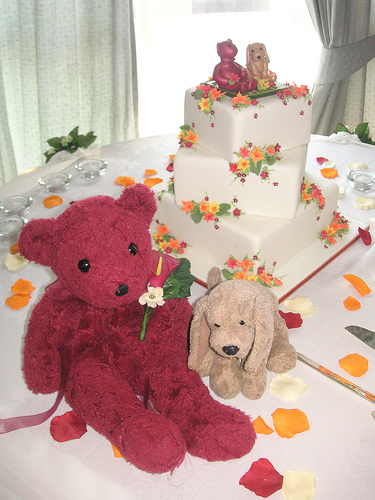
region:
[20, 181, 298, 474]
two plushies on a white tablecloth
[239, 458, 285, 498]
a red rose petal on a tablecloth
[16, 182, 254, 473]
a red teddy bear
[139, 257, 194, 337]
a boutonniere on a red teddy bear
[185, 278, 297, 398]
a plushie dog next to a red teddy bear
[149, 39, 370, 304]
a wedding cake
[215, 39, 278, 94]
figurines of a teddy bear and a dog on top of a wedding cake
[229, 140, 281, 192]
candy flowers on a white wedding cake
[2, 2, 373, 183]
gray drapes on the window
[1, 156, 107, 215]
small glass bowl on a table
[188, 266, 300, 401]
Brown fuzzy stuffed animal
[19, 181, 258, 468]
Red fuzzy stuffed animal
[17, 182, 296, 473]
Red fuzzy stuffed animal next to brown fuzzy stuffed animal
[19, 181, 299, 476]
Brown fuzzy stuffed animal next to red fuzzy stuffed animal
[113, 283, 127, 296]
Black nose on red fuzzy stuffed animal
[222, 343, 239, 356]
Black nose on brown fuzzy stuffed animal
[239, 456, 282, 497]
Red flower petal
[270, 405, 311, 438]
Orange flower petal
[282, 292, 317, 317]
White flower petal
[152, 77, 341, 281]
Flowers on white wedding cake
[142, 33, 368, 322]
cake on the table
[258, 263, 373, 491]
petals on the table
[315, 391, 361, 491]
the tablecloth is white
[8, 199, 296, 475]
the toys are red and brown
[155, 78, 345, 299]
the cake is 3 layers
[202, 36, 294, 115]
red and gold decoration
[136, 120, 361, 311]
flowers on the cake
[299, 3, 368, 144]
the curtain is open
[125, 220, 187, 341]
a flower on the bear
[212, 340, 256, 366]
the nose is black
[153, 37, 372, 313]
wedding cake with red bear and cream dog on top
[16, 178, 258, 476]
red-colored stuff bear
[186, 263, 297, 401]
cream colored stuffed dog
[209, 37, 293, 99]
bear and dog cake topper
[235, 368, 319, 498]
multi-colored rose petals scattered on a table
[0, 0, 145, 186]
light green curtains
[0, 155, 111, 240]
glass candle holders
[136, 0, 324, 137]
sunlight coming through a window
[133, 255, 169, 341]
boutineer worn by red stuffed bear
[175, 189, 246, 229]
orange, red and yellow flowers on a wedding cake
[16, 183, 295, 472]
the stuffed animals on the table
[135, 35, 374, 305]
the decorated wedding cake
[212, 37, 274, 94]
the topping on the cake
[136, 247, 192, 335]
the flower on the bigger stuffed animal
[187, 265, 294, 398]
the smaller stuffed animal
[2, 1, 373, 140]
the curtains in the back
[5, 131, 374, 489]
the white table cloth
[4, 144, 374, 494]
the flower petals sprinkled on the table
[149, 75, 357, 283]
the flowers decorated on the cake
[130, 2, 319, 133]
the light shining in from the window